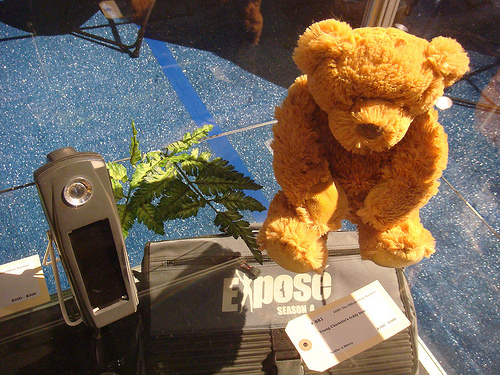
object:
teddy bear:
[257, 17, 468, 274]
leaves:
[104, 115, 267, 265]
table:
[0, 8, 497, 374]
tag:
[284, 278, 413, 372]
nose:
[354, 121, 381, 138]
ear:
[427, 35, 471, 87]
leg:
[358, 203, 437, 268]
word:
[222, 269, 333, 316]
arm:
[267, 81, 349, 233]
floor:
[0, 29, 500, 375]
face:
[293, 20, 470, 156]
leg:
[257, 190, 330, 273]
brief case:
[139, 222, 419, 375]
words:
[319, 310, 366, 334]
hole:
[303, 343, 308, 347]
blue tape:
[135, 17, 224, 137]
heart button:
[394, 38, 406, 49]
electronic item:
[33, 146, 140, 331]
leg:
[130, 8, 152, 58]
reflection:
[237, 0, 264, 48]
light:
[434, 121, 450, 196]